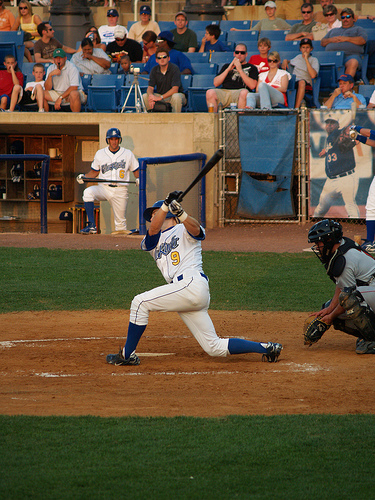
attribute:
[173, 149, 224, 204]
bat — black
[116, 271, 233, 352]
pants — white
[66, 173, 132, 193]
bat — horizontally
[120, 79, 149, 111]
stand — silver , tripod 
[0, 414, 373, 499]
green grass — lush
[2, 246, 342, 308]
green grass — lush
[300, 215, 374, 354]
catcher — crouching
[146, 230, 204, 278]
shirt — white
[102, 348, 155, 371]
shoes — black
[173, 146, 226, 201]
baseball bat — black 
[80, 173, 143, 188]
baseball bat — black 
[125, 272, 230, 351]
pants — player's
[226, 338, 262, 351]
sock — blue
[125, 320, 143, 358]
sock — blue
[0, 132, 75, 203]
storage cubicles — wooden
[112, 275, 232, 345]
pants — white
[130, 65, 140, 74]
camera — small